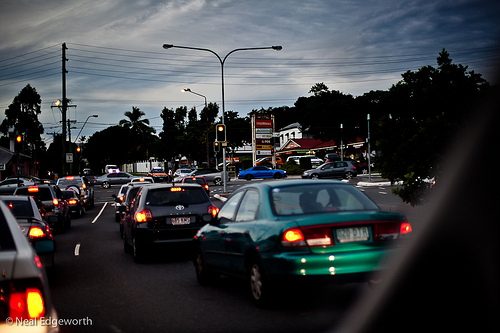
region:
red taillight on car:
[282, 226, 303, 242]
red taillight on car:
[398, 223, 412, 235]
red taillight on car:
[22, 289, 43, 321]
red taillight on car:
[27, 228, 45, 244]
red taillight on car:
[51, 195, 60, 208]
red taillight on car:
[66, 196, 76, 208]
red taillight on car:
[78, 178, 88, 190]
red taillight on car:
[135, 210, 145, 225]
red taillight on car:
[211, 206, 218, 214]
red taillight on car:
[203, 182, 210, 191]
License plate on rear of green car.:
[332, 224, 372, 246]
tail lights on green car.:
[277, 230, 331, 246]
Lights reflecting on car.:
[296, 254, 338, 274]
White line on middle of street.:
[85, 198, 107, 228]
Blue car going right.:
[237, 161, 287, 182]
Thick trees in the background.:
[95, 96, 220, 153]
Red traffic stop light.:
[72, 140, 84, 155]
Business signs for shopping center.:
[250, 110, 276, 155]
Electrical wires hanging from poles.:
[132, 55, 198, 86]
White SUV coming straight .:
[102, 160, 125, 175]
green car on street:
[194, 180, 410, 308]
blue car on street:
[238, 163, 285, 182]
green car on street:
[303, 160, 356, 180]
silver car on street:
[1, 202, 60, 332]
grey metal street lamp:
[162, 38, 283, 191]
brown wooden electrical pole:
[59, 43, 69, 177]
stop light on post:
[217, 124, 225, 144]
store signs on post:
[253, 117, 273, 158]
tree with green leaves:
[372, 51, 492, 181]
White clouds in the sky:
[1, 0, 497, 147]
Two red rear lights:
[130, 200, 220, 221]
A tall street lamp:
[156, 37, 282, 188]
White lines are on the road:
[71, 195, 113, 255]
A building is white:
[271, 116, 301, 146]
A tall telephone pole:
[55, 37, 75, 139]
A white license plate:
[330, 220, 375, 245]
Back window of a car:
[140, 180, 211, 207]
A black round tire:
[238, 250, 275, 310]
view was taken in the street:
[46, 86, 399, 325]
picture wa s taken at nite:
[48, 91, 401, 331]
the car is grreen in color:
[245, 177, 403, 332]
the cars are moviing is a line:
[96, 117, 320, 331]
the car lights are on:
[279, 214, 436, 287]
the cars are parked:
[243, 152, 344, 180]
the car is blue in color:
[228, 150, 293, 186]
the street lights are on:
[193, 122, 254, 156]